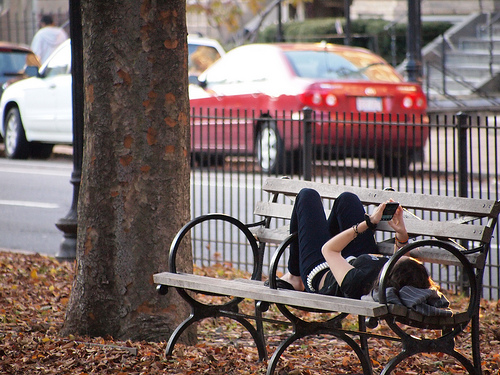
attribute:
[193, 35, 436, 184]
car — red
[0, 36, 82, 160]
car — white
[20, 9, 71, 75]
person — walking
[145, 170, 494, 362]
bench — wooden, wood, metal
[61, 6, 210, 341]
tree — gray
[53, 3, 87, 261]
pole — black, metal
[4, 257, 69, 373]
leaves — dead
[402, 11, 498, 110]
steps — gray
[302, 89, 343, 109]
lights — red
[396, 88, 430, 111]
lights — red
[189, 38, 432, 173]
car — red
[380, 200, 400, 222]
cell phone — black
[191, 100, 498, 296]
fence — black, iron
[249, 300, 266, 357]
pole — black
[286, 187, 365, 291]
pants — black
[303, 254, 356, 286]
belt — silver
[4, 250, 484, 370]
leaves — brown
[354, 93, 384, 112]
plate — white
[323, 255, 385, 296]
shirt — black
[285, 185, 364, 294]
jeans — black